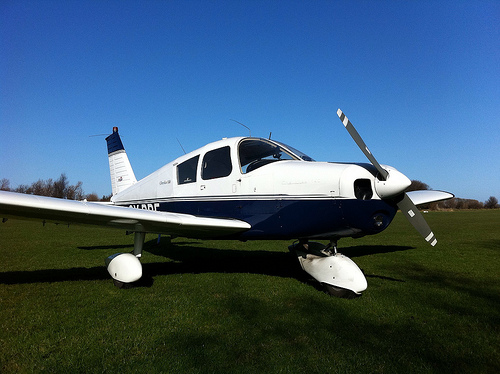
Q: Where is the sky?
A: Above the airplane.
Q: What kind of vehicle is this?
A: Jet.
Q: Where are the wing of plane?
A: On side.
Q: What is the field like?
A: Grassy green.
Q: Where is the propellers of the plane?
A: Front.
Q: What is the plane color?
A: White and black.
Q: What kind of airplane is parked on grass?
A: Blue and white.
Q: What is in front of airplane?
A: Propeller.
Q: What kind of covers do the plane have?
A: White.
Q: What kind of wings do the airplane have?
A: White.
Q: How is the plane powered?
A: Propeller.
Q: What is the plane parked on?
A: Grass.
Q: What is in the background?
A: Trees.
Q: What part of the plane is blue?
A: Bottom.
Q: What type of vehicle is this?
A: Airplane.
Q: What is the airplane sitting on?
A: Grass.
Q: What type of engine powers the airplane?
A: Propeller.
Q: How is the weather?
A: Sunny.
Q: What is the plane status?
A: Parked.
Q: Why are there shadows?
A: Sunny.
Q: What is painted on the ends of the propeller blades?
A: Stripes.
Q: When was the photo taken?
A: Afternoon.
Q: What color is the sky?
A: Blue.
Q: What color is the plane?
A: Blue and white.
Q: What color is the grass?
A: Green.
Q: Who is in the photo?
A: No one.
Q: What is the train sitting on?
A: Grass.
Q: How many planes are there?
A: One.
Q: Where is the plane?
A: On a field.